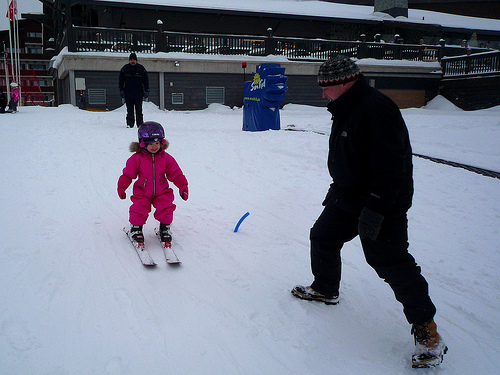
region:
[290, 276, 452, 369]
Man wearing shoes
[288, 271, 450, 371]
Man wearing brown shoes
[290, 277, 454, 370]
Man wearing boots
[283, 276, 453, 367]
Man is wearing boots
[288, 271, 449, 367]
Man wearing brown boots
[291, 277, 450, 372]
Man is wearing brown boots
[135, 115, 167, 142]
Girl wearing a purple helmet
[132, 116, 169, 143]
Girl is wearing a purple helmet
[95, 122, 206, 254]
child in pink clothing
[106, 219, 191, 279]
pair of skis on child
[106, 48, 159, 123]
man in black clothing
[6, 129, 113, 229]
ground covered in snow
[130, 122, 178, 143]
purple safety helmet on child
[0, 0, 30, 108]
tall metal flag poles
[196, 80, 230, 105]
window on side of building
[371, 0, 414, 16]
stone chimney on house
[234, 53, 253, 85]
red light on machinery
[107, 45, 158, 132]
The man is wearing a cap.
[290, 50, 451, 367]
The man is wearing a cap.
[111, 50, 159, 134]
The man is wearing gloves.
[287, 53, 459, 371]
The man is wearing gloves.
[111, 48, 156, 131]
The man is wearing snow pants.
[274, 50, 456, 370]
The man is wearing snow pants.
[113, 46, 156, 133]
The man is wearing a jacket.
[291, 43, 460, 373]
The man is wearing a jacket.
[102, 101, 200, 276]
The little girl is wearing skis.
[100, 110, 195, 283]
The little girl is wearing a helmet.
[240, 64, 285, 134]
blue sign for ski park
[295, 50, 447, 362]
man watching child ski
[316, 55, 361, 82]
man wears grey knitted beanie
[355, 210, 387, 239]
grey knitted gloves on hands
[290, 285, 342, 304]
brown color snow boot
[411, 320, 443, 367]
brown color snow boot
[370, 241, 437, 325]
black snow pants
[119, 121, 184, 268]
girl skiing on snow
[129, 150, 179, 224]
pink snow suit on girl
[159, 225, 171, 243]
shoe strapped in to skii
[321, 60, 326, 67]
white dot on winter hat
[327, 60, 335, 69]
white dot on winter hat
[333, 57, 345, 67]
white dot on winter hat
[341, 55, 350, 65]
white dot on winter hat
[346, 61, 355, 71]
white dot on winter hat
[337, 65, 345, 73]
white dot on winter hat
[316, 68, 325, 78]
white dot on winter hat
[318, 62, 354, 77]
white dots on winter hat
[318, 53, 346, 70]
white dots on winter hat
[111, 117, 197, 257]
a person is standing up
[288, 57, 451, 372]
a person is standing up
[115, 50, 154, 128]
a person is standing up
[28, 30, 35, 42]
a window on a building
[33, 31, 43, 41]
a window on a building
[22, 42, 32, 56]
a window on a building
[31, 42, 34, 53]
a window on a building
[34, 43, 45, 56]
a window on a building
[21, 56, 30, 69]
a window on a building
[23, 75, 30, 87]
a window on a building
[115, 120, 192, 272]
A little girl on skiis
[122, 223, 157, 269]
A ski in the snow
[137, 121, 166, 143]
A helmet on a little girl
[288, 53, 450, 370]
A man standing in the snow